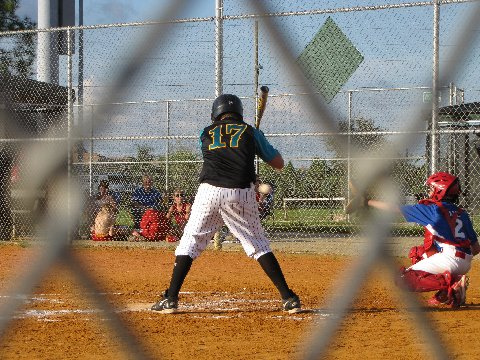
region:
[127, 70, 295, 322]
kid playing baseball on field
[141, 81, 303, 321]
kid holding baseball bat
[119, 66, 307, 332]
kid in the batters box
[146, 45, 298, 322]
kids about to swing bat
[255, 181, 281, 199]
baseball in the air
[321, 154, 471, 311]
kid playing catcher position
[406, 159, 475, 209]
red catchers mask on face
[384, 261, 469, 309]
red shin guards on legs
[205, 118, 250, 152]
number on back of jersey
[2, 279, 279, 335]
white chalk outlines of box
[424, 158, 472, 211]
red catchers protective helmet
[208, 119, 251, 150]
green number seventeen on shirt back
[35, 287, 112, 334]
white line painted on dirt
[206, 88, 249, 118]
black batter's helmet on boys head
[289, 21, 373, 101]
green diamond pattern on metal fence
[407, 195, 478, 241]
blue tshirt with white number on it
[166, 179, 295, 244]
white pants with black stripes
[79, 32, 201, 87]
silver metal chain link fence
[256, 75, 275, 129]
brown wooden bat over right shoulder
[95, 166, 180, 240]
spectators located outside of fence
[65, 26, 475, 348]
kids playing baseball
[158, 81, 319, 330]
batter standing at home plate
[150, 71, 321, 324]
baseball player holding a bat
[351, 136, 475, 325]
hind catcher squatting at home plate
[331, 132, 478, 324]
hind catcher holding out baseball mitt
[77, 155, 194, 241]
spectators watching a baseball game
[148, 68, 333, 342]
baseball player wearing a black and white jersey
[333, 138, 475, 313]
baseball player wearing a blue and white jersey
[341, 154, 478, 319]
hind catcher wearing red equipment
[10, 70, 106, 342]
metal fencing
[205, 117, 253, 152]
the number seventeen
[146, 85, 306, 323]
a person playing baseball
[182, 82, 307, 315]
a person at bat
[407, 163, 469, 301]
a person playing baseball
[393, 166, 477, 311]
a person being the catcher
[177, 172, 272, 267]
baseball pants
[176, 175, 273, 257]
white and black striped baseball pants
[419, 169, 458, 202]
a red catchers helmet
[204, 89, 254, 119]
a black batter's helmet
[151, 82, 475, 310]
two people playing baseball together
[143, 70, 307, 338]
This is a person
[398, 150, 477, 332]
This is a person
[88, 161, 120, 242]
This is a person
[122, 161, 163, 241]
This is a person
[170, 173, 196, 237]
This is a person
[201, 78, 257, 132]
Head of a person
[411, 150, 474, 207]
Head of a person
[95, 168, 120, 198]
Head of a person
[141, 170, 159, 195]
Head of a person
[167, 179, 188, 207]
Head of a person